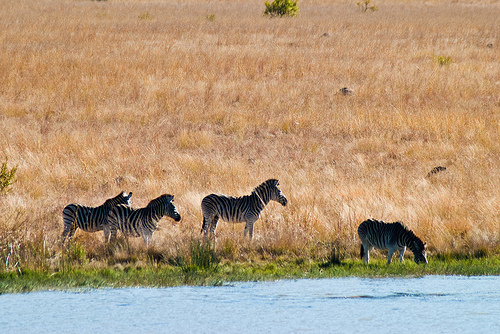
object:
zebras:
[101, 194, 182, 250]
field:
[1, 0, 498, 265]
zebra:
[356, 218, 428, 268]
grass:
[398, 260, 497, 278]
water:
[1, 272, 499, 333]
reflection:
[360, 274, 426, 295]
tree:
[262, 0, 301, 19]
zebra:
[200, 179, 289, 241]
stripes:
[211, 194, 230, 223]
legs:
[386, 250, 397, 267]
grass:
[29, 99, 488, 182]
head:
[267, 179, 288, 208]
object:
[424, 166, 447, 179]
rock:
[338, 86, 355, 96]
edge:
[0, 260, 499, 293]